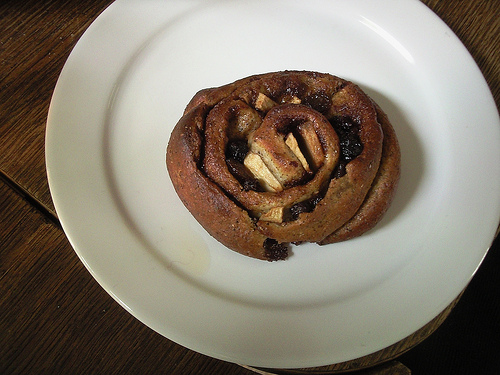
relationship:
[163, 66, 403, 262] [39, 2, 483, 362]
cinnamon bun on plate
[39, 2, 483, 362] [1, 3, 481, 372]
plate on table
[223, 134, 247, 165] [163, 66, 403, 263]
raisin on cinnamon bun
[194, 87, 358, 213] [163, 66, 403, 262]
swirls in cinnamon bun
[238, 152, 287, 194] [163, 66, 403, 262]
apple chunk in cinnamon bun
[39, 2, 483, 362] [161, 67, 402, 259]
plate with roll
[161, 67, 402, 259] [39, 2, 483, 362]
roll sitting on top of plate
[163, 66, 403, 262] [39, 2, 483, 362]
cinnamon bun sitting on top of plate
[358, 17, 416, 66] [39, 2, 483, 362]
light reflecting on plate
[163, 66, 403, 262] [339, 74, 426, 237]
cinnamon bun casting shadow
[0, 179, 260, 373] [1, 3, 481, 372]
section belonging to table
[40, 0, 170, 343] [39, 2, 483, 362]
left side belonging to plate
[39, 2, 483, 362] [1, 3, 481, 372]
plate sitting on top of table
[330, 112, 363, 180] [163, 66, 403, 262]
filling baked inside cinnamon bun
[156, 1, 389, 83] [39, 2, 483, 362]
section belonging to plate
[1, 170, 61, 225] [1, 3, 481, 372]
seam on table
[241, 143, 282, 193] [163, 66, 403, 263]
filling in cinnamon bun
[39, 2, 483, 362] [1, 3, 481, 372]
plate on top of table